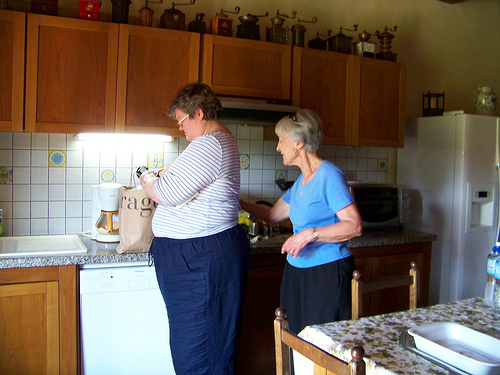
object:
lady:
[240, 111, 365, 330]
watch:
[309, 225, 320, 244]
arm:
[309, 171, 363, 244]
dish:
[400, 319, 498, 373]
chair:
[271, 307, 366, 374]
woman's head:
[275, 107, 325, 164]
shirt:
[279, 162, 357, 270]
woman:
[136, 81, 246, 374]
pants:
[150, 224, 249, 375]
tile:
[13, 165, 29, 186]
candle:
[97, 184, 124, 212]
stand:
[103, 209, 122, 236]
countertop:
[0, 233, 453, 269]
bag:
[114, 180, 160, 255]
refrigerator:
[400, 109, 500, 301]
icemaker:
[463, 180, 497, 231]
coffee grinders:
[374, 23, 399, 60]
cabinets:
[292, 47, 408, 148]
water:
[483, 246, 500, 311]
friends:
[136, 81, 365, 374]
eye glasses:
[176, 114, 190, 124]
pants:
[280, 257, 358, 335]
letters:
[142, 197, 157, 218]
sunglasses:
[290, 111, 302, 129]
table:
[298, 295, 500, 375]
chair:
[350, 261, 420, 317]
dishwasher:
[78, 261, 180, 374]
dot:
[109, 275, 112, 279]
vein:
[303, 148, 313, 178]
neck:
[287, 155, 325, 170]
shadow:
[405, 23, 444, 114]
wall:
[213, 4, 498, 109]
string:
[146, 244, 158, 266]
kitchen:
[0, 2, 500, 374]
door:
[450, 114, 495, 299]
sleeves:
[327, 171, 357, 214]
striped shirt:
[151, 134, 242, 241]